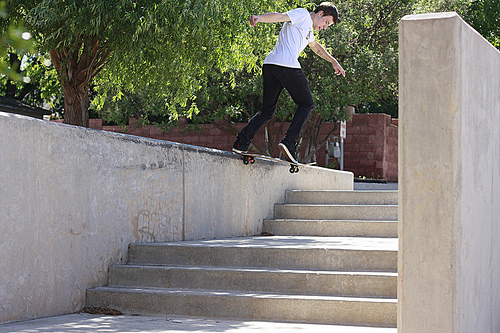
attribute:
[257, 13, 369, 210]
man — skating, air, light, young, skateboarding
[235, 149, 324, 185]
board — skate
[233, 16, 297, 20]
hand — behind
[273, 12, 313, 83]
shirt — white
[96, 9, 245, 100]
tree — leafy, green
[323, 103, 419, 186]
wall — stone, brick, gray, red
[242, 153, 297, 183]
wheels — found, black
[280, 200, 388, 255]
steps — gray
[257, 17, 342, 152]
he — jumping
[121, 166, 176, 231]
wall — gray, grey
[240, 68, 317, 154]
pants — black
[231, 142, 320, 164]
shoes — black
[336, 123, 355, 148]
lettering — red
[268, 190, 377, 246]
stairs — concrete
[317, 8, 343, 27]
hair — brown